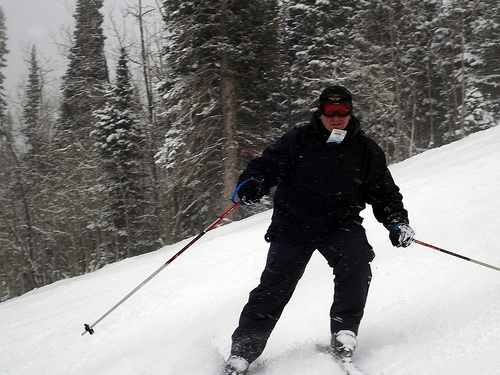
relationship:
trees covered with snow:
[0, 0, 275, 225] [156, 125, 181, 165]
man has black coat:
[224, 85, 414, 372] [238, 114, 408, 243]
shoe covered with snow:
[330, 330, 361, 354] [144, 327, 194, 370]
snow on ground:
[113, 329, 188, 371] [367, 319, 434, 371]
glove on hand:
[238, 184, 270, 207] [232, 176, 272, 207]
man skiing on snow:
[224, 85, 414, 372] [2, 281, 205, 372]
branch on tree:
[188, 112, 223, 124] [160, 0, 281, 237]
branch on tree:
[174, 137, 223, 162] [160, 0, 281, 237]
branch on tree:
[179, 62, 215, 80] [160, 0, 281, 237]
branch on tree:
[240, 103, 261, 118] [160, 0, 281, 237]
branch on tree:
[104, 208, 122, 223] [78, 185, 115, 268]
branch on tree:
[94, 217, 113, 232] [78, 185, 115, 268]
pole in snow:
[71, 270, 155, 345] [406, 155, 477, 225]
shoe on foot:
[319, 327, 370, 354] [333, 320, 357, 362]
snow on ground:
[0, 123, 499, 374] [377, 260, 488, 373]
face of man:
[320, 88, 351, 133] [223, 81, 398, 373]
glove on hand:
[387, 216, 417, 257] [387, 216, 418, 248]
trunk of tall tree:
[216, 60, 241, 222] [150, 0, 288, 230]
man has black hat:
[224, 85, 414, 372] [316, 85, 352, 109]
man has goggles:
[224, 85, 414, 372] [317, 97, 354, 117]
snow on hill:
[0, 123, 499, 374] [2, 110, 498, 371]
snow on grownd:
[0, 123, 499, 374] [0, 120, 498, 374]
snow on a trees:
[151, 117, 196, 171] [73, 34, 334, 116]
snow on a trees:
[149, 70, 172, 88] [152, 4, 275, 234]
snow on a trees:
[200, 97, 216, 124] [267, 0, 396, 178]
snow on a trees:
[91, 100, 132, 147] [89, 40, 156, 269]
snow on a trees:
[445, 42, 495, 131] [431, 0, 498, 150]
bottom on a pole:
[78, 320, 98, 340] [67, 195, 254, 346]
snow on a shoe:
[329, 325, 359, 351] [330, 330, 361, 354]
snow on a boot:
[222, 355, 251, 365] [227, 348, 248, 373]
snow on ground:
[0, 123, 499, 374] [0, 250, 239, 374]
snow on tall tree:
[87, 82, 155, 155] [82, 46, 170, 259]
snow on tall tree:
[87, 82, 155, 155] [56, 4, 110, 265]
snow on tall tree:
[20, 99, 34, 124] [152, 0, 284, 230]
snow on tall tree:
[162, 20, 209, 172] [16, 39, 52, 182]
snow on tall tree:
[87, 211, 108, 276] [0, 4, 10, 307]